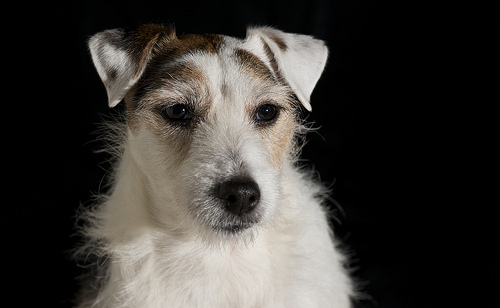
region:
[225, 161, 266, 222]
Black nose on a Jack Russel.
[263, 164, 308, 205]
Black nose on a Jack Russel.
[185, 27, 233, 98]
Black nose on a Jack Russel.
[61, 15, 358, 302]
A white and brown spotted dog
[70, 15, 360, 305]
A white and brown spotted dog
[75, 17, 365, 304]
A white and brown spotted dog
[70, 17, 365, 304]
A white and brown spotted dog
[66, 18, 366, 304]
A white and brown spotted dog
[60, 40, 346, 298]
dog is in picture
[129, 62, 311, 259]
the dog is closer to the camera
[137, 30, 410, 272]
the picture was taken at night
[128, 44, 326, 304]
the dog is white in color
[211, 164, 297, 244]
the nose is black in color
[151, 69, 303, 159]
the eyes are opened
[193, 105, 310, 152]
the eyes are black in color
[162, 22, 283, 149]
the forehaed has some brown marks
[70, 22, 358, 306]
A white and brown spotted dog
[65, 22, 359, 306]
A white and brown spotted dog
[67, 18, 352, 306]
A white and brown spotted dog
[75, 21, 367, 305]
A white and brown spotted dog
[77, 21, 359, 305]
A white and brown spotted dog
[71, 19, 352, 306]
A white and brown spotted dog